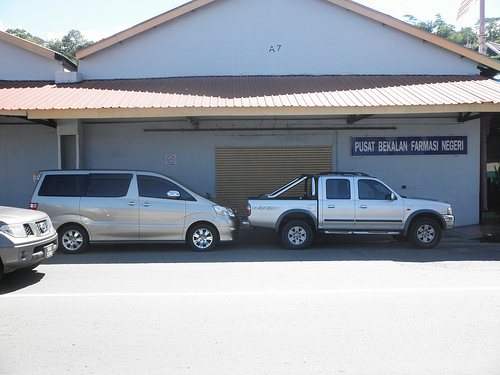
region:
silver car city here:
[65, 61, 397, 322]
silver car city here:
[91, 82, 263, 330]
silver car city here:
[174, 106, 440, 302]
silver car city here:
[88, 145, 454, 245]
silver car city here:
[1, 179, 428, 264]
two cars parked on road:
[25, 156, 447, 264]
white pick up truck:
[255, 163, 468, 255]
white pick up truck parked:
[244, 159, 454, 248]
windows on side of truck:
[325, 178, 389, 195]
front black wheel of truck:
[406, 218, 442, 245]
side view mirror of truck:
[389, 193, 399, 200]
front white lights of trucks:
[442, 204, 455, 216]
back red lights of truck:
[248, 204, 253, 212]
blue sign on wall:
[350, 137, 473, 160]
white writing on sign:
[348, 137, 465, 157]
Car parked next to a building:
[248, 168, 455, 245]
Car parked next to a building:
[26, 164, 238, 252]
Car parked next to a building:
[0, 198, 60, 278]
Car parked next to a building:
[25, 165, 456, 251]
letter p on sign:
[351, 140, 360, 155]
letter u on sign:
[357, 139, 366, 153]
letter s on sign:
[362, 138, 369, 151]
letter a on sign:
[366, 137, 373, 152]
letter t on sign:
[368, 138, 377, 152]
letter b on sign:
[376, 137, 383, 154]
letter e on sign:
[381, 140, 388, 152]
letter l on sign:
[394, 138, 400, 153]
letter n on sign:
[401, 136, 409, 153]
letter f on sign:
[409, 137, 416, 153]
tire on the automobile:
[403, 217, 443, 246]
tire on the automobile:
[281, 223, 311, 247]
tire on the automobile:
[187, 224, 216, 249]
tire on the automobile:
[56, 223, 88, 249]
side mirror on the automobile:
[159, 189, 179, 201]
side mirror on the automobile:
[384, 193, 398, 203]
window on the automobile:
[326, 176, 348, 201]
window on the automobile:
[360, 179, 387, 200]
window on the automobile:
[139, 179, 186, 204]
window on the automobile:
[87, 169, 133, 204]